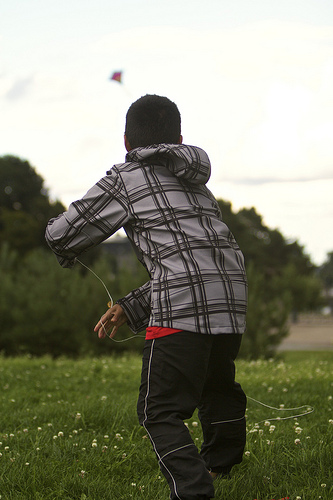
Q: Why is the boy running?
A: He is playing.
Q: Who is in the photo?
A: A boy.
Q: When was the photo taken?
A: Daytime.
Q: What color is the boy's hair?
A: Black.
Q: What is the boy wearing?
A: A jacket.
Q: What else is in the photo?
A: Grass.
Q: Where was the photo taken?
A: The field.